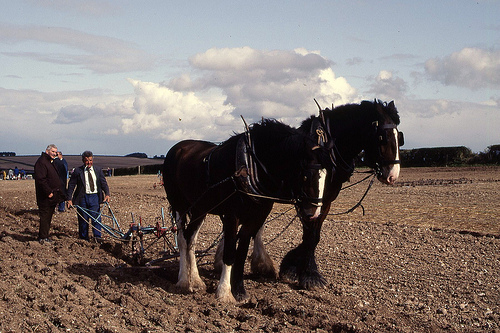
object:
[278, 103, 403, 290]
horses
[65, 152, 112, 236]
farmers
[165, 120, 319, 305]
clydesdales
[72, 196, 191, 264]
work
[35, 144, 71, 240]
man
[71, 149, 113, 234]
man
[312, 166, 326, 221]
markings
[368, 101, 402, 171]
faces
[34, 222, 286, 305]
soil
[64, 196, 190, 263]
plowed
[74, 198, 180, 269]
plow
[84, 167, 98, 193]
tie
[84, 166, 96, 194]
shirt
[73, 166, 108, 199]
coat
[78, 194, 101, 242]
jeans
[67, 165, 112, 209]
suit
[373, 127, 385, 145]
blinders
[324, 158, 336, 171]
focus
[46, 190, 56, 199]
hand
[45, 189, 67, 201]
pocket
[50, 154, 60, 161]
beard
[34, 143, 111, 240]
people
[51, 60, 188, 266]
background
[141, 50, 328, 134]
clouds